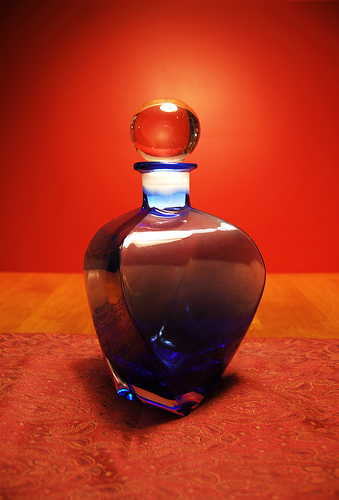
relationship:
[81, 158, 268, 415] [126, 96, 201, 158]
carafe has glass top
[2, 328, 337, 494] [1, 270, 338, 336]
cloth on table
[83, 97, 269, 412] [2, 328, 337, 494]
vase on cloth